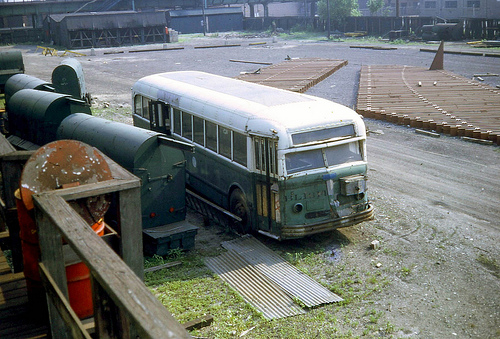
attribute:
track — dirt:
[5, 37, 499, 337]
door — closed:
[242, 129, 286, 240]